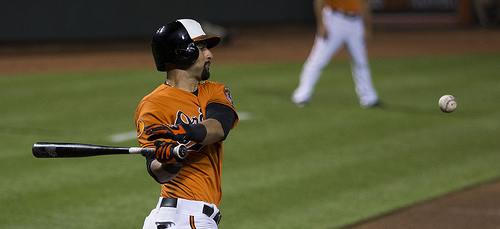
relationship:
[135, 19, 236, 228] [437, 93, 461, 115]
man hitting ball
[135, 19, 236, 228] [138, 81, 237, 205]
man has shirt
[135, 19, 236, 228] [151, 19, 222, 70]
man wearing helmet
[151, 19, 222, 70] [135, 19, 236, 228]
helmet on man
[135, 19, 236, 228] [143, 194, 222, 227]
man has pants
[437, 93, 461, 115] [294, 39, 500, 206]
ball in air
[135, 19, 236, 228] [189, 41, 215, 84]
man has face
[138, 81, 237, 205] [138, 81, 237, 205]
shirt under shirt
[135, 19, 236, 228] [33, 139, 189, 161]
man has bat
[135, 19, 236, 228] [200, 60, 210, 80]
man has beard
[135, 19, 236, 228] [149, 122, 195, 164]
man wearing gloves